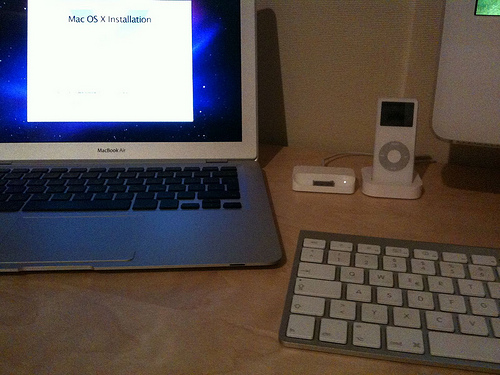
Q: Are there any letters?
A: Yes, there are letters.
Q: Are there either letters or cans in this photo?
A: Yes, there are letters.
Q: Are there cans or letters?
A: Yes, there are letters.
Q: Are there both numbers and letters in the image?
A: No, there are letters but no numbers.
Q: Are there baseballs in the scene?
A: No, there are no baseballs.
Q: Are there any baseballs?
A: No, there are no baseballs.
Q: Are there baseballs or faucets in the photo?
A: No, there are no baseballs or faucets.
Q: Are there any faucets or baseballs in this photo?
A: No, there are no baseballs or faucets.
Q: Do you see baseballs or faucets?
A: No, there are no baseballs or faucets.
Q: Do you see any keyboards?
A: Yes, there is a keyboard.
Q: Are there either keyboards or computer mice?
A: Yes, there is a keyboard.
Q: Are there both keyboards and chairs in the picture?
A: No, there is a keyboard but no chairs.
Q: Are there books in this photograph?
A: No, there are no books.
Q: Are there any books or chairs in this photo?
A: No, there are no books or chairs.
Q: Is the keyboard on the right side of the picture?
A: Yes, the keyboard is on the right of the image.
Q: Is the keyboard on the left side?
A: No, the keyboard is on the right of the image.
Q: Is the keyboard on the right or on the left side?
A: The keyboard is on the right of the image.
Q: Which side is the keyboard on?
A: The keyboard is on the right of the image.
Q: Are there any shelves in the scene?
A: No, there are no shelves.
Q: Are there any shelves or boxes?
A: No, there are no shelves or boxes.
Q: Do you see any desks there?
A: Yes, there is a desk.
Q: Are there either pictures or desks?
A: Yes, there is a desk.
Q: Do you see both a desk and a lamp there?
A: No, there is a desk but no lamps.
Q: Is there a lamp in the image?
A: No, there are no lamps.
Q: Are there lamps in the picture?
A: No, there are no lamps.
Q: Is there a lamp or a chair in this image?
A: No, there are no lamps or chairs.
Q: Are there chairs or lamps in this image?
A: No, there are no lamps or chairs.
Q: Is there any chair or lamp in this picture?
A: No, there are no lamps or chairs.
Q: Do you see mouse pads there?
A: Yes, there is a mouse pad.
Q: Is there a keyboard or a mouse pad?
A: Yes, there is a mouse pad.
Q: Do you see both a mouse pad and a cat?
A: No, there is a mouse pad but no cats.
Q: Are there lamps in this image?
A: No, there are no lamps.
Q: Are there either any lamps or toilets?
A: No, there are no lamps or toilets.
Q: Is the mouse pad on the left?
A: Yes, the mouse pad is on the left of the image.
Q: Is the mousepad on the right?
A: No, the mousepad is on the left of the image.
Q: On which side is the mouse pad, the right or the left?
A: The mouse pad is on the left of the image.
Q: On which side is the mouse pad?
A: The mouse pad is on the left of the image.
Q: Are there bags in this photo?
A: No, there are no bags.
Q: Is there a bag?
A: No, there are no bags.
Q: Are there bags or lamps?
A: No, there are no bags or lamps.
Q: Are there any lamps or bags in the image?
A: No, there are no bags or lamps.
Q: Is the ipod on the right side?
A: Yes, the ipod is on the right of the image.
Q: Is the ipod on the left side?
A: No, the ipod is on the right of the image.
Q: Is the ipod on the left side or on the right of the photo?
A: The ipod is on the right of the image.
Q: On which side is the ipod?
A: The ipod is on the right of the image.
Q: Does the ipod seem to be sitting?
A: Yes, the ipod is sitting.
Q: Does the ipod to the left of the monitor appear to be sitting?
A: Yes, the ipod is sitting.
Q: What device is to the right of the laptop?
A: The device is an ipod.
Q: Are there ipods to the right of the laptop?
A: Yes, there is an ipod to the right of the laptop.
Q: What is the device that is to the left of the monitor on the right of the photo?
A: The device is an ipod.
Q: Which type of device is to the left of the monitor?
A: The device is an ipod.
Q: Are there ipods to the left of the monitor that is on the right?
A: Yes, there is an ipod to the left of the monitor.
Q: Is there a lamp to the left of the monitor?
A: No, there is an ipod to the left of the monitor.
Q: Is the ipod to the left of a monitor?
A: Yes, the ipod is to the left of a monitor.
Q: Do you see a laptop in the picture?
A: Yes, there is a laptop.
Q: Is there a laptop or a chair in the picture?
A: Yes, there is a laptop.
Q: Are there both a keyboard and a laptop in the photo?
A: Yes, there are both a laptop and a keyboard.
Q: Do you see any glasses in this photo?
A: No, there are no glasses.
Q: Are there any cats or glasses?
A: No, there are no glasses or cats.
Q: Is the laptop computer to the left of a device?
A: Yes, the laptop computer is to the left of a device.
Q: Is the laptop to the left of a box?
A: No, the laptop is to the left of a device.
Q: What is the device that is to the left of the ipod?
A: The device is a laptop.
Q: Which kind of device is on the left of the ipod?
A: The device is a laptop.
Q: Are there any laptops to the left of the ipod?
A: Yes, there is a laptop to the left of the ipod.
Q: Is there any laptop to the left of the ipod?
A: Yes, there is a laptop to the left of the ipod.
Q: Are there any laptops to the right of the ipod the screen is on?
A: No, the laptop is to the left of the ipod.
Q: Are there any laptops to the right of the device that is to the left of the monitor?
A: No, the laptop is to the left of the ipod.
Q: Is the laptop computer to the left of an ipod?
A: Yes, the laptop computer is to the left of an ipod.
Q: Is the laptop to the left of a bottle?
A: No, the laptop is to the left of an ipod.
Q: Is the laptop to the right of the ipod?
A: No, the laptop is to the left of the ipod.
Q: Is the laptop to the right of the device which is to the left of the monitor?
A: No, the laptop is to the left of the ipod.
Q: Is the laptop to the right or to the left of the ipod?
A: The laptop is to the left of the ipod.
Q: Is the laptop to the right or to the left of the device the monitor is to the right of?
A: The laptop is to the left of the ipod.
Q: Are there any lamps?
A: No, there are no lamps.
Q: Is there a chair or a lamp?
A: No, there are no lamps or chairs.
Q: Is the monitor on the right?
A: Yes, the monitor is on the right of the image.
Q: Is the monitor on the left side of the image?
A: No, the monitor is on the right of the image.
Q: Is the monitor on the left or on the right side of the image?
A: The monitor is on the right of the image.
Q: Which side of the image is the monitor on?
A: The monitor is on the right of the image.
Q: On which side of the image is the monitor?
A: The monitor is on the right of the image.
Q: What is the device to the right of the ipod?
A: The device is a monitor.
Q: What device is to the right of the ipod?
A: The device is a monitor.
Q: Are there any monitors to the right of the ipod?
A: Yes, there is a monitor to the right of the ipod.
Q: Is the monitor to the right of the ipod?
A: Yes, the monitor is to the right of the ipod.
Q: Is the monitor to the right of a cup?
A: No, the monitor is to the right of the ipod.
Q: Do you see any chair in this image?
A: No, there are no chairs.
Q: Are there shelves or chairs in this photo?
A: No, there are no chairs or shelves.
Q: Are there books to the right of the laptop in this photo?
A: No, there is a device to the right of the laptop.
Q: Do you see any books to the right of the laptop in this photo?
A: No, there is a device to the right of the laptop.